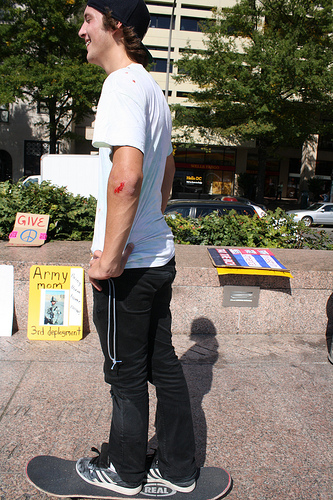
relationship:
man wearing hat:
[77, 0, 200, 494] [85, 1, 154, 65]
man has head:
[77, 0, 200, 494] [76, 1, 156, 67]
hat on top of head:
[85, 1, 154, 65] [76, 1, 156, 67]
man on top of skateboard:
[77, 0, 200, 494] [25, 454, 232, 500]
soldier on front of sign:
[44, 293, 62, 326] [25, 263, 87, 342]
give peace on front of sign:
[18, 213, 45, 242] [5, 212, 50, 249]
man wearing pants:
[77, 0, 200, 494] [91, 255, 200, 488]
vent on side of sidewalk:
[219, 283, 262, 308] [1, 328, 332, 499]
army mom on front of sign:
[33, 266, 69, 291] [25, 263, 87, 342]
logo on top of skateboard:
[139, 482, 177, 498] [25, 454, 232, 500]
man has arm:
[77, 0, 200, 494] [87, 140, 144, 292]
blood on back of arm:
[113, 179, 125, 197] [87, 140, 144, 292]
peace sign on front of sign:
[17, 227, 37, 243] [5, 212, 50, 249]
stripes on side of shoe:
[88, 466, 117, 486] [75, 440, 144, 497]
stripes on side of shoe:
[145, 462, 161, 483] [145, 447, 197, 492]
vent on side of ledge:
[219, 283, 262, 308] [1, 239, 332, 332]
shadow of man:
[144, 316, 219, 467] [77, 0, 200, 494]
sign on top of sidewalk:
[25, 263, 87, 342] [1, 328, 332, 499]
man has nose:
[77, 0, 200, 494] [77, 21, 87, 37]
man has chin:
[77, 0, 200, 494] [83, 51, 94, 63]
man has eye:
[77, 0, 200, 494] [84, 14, 94, 26]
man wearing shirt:
[77, 0, 200, 494] [88, 62, 176, 268]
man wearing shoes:
[77, 0, 200, 494] [76, 442, 196, 495]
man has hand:
[77, 0, 200, 494] [85, 241, 133, 294]